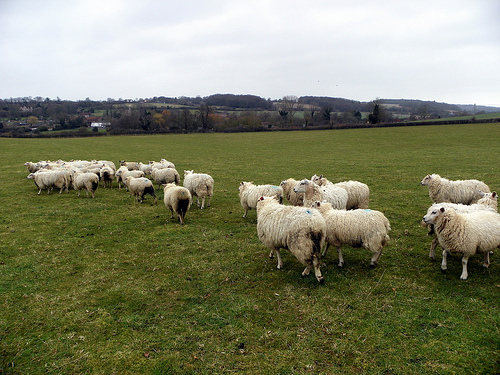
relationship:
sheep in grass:
[246, 192, 333, 289] [88, 273, 147, 308]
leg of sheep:
[441, 245, 472, 278] [246, 192, 333, 289]